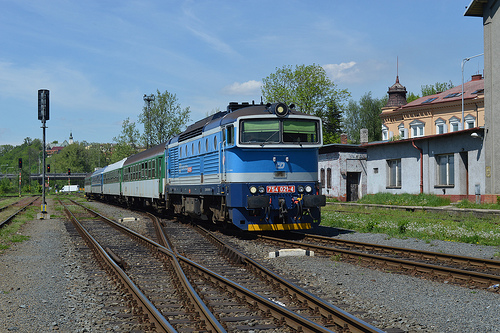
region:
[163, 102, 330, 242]
a white and blue passenger train engine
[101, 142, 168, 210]
green and white passenger train car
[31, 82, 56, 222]
a stop light on a metal pole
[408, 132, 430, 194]
a red rain gutter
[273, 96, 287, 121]
a round train head light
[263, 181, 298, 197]
white letters and numbers on the front of a train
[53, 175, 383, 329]
metal and wood train tracks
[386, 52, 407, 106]
a tower on a building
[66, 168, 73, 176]
a red stop light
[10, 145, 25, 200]
a stop light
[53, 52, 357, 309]
this is a train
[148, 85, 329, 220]
front train car is blue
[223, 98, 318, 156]
front window on train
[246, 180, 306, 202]
red plate on train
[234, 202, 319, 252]
yellow trim on train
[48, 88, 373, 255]
this is a passenger train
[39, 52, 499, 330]
train is on the tracks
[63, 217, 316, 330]
double sets of tracks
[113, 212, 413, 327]
gravel on the tracks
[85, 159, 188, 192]
windows on the train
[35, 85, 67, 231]
Light by train tracks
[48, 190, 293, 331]
Train tracks by a train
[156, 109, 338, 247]
Blue engine on a train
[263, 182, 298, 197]
Red lincense on a train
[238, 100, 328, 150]
Windows on a train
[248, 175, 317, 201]
Lights on a train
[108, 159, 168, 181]
Windows on a train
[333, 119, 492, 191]
Building by train tracks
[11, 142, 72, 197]
Lights by train tracks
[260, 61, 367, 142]
Tree by buildings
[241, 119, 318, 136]
Shades to help block the sun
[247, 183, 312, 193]
Lights on front of the train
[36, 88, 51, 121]
Traffic signal for the trains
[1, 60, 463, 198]
A bunch of green trees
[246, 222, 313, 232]
Yellow paint on the front of the train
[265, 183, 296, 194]
Identifying numbers on the front of the train.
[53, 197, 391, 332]
Tracks are criss crossing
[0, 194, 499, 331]
Several parallel tracks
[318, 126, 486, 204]
Shoddy looking building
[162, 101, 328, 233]
The engine is mostly blue.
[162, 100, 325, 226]
mostly blue locomotive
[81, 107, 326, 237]
locomotive hauling passenger cars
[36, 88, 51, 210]
traffic light on thin tall pole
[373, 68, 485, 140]
building is yellow with red roof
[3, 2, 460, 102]
sky is bright blue with small clouds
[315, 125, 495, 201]
grey one story building near train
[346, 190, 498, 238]
ground around building made of grass and gravel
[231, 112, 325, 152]
shades on locomotive windows are halfway down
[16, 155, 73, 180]
3 traffic lights in the background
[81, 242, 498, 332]
multiple train tracks standing on wood beams and gravel